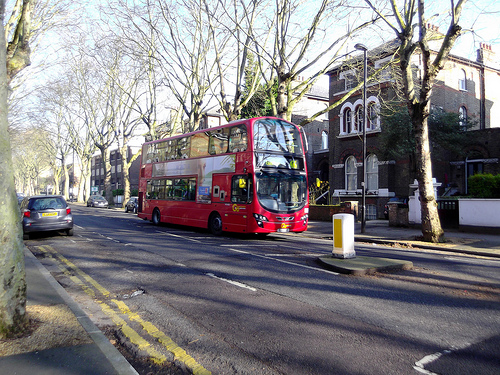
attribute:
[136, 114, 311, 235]
bus — double decker, red, double stacked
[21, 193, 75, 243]
car — compact, dark, parked, grey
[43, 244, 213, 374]
line — yellow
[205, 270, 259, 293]
line — white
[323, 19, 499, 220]
building — large, dark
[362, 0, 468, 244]
tree — bare, large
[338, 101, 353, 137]
window — framed, arched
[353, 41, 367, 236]
light post — tall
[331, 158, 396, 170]
trim — white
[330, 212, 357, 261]
street marker — white, yellow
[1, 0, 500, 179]
sky — daytime